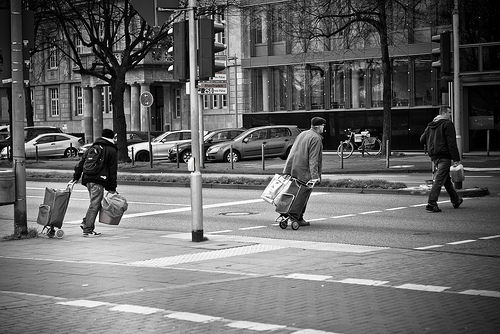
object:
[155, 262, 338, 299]
street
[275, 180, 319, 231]
man dragging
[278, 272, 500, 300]
white dashes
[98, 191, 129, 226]
bag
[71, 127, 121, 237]
man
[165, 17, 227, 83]
traffic lights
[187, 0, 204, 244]
pole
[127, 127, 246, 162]
cars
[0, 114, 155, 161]
in the lot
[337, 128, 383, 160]
bike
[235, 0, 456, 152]
building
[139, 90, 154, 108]
"the sign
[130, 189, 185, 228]
of the road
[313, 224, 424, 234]
shade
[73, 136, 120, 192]
jacket is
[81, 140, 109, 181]
back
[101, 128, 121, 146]
cape is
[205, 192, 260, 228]
road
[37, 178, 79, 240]
briefcase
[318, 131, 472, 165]
roadside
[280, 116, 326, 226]
man in the middle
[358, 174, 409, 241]
crossway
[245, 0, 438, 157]
tree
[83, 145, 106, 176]
backpack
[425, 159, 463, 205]
man is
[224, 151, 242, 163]
front wheel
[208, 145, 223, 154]
headlight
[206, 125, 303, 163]
car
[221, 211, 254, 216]
manhole cover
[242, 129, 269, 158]
driver's door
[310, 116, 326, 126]
cap is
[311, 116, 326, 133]
head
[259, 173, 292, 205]
large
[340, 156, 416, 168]
curb